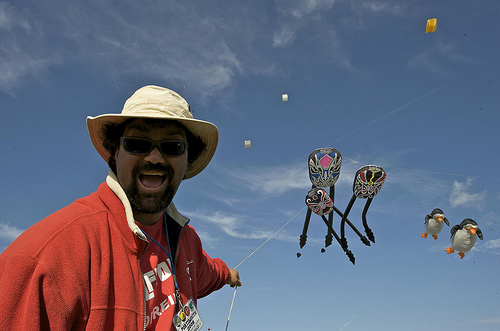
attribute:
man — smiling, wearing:
[59, 84, 268, 277]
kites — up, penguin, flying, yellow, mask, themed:
[281, 116, 433, 282]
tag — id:
[155, 261, 214, 330]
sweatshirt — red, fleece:
[22, 188, 190, 312]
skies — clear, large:
[75, 11, 337, 97]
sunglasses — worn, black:
[123, 140, 202, 166]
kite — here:
[344, 160, 399, 215]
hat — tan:
[99, 74, 235, 156]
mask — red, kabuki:
[357, 165, 384, 183]